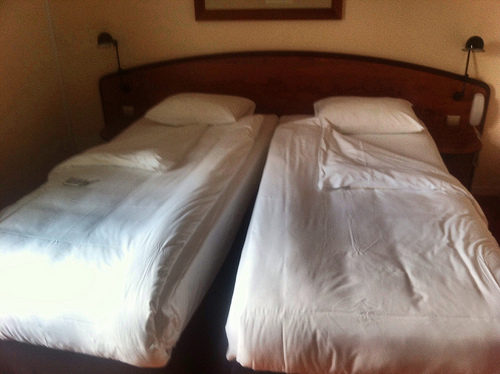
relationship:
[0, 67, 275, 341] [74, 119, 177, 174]
bed with comforter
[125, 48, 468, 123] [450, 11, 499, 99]
headboard has lamps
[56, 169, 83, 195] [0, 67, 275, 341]
object on bed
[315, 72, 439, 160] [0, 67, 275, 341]
pillow on bed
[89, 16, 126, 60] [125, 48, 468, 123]
lamp on headboard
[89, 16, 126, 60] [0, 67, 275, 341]
lamp on bed